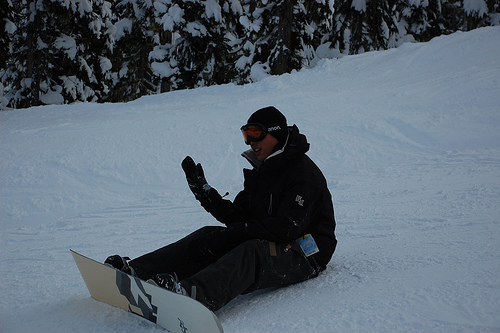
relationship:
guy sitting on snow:
[103, 106, 338, 313] [50, 113, 160, 242]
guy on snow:
[103, 106, 338, 313] [32, 119, 91, 187]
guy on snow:
[103, 106, 338, 313] [312, 78, 395, 203]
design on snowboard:
[109, 271, 156, 321] [68, 246, 222, 331]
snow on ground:
[240, 307, 307, 327] [287, 262, 483, 328]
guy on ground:
[103, 106, 338, 313] [12, 92, 492, 331]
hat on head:
[242, 106, 287, 141] [242, 105, 292, 156]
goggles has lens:
[240, 124, 283, 144] [244, 125, 277, 137]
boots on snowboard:
[103, 247, 211, 300] [52, 245, 223, 330]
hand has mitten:
[174, 143, 213, 193] [178, 152, 216, 203]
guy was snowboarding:
[103, 106, 338, 313] [16, 59, 431, 330]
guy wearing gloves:
[103, 106, 338, 313] [179, 153, 214, 203]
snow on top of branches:
[3, 0, 498, 106] [3, 0, 498, 107]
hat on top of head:
[242, 107, 287, 136] [241, 104, 290, 153]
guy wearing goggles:
[103, 106, 338, 313] [240, 124, 283, 144]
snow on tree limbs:
[1, 1, 498, 86] [0, 5, 487, 112]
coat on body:
[203, 122, 339, 278] [105, 104, 337, 311]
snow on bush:
[36, 31, 133, 102] [53, 27, 172, 86]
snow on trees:
[3, 0, 498, 106] [3, 0, 497, 107]